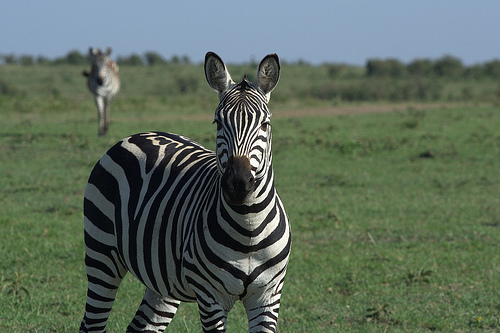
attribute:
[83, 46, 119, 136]
zebra — white , black , striped 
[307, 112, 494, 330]
grass — long , green, yellow 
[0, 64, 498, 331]
grass — yellow , green , long , brown , short 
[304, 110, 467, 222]
grass — yellow , green , long 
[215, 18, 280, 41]
clouds — white 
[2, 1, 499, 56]
sky — blue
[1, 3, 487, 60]
sky — blue 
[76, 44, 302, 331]
zebra — white , black , striped 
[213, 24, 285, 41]
clouds — white 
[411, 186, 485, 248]
grass — short , green, brown 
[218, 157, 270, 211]
nose — black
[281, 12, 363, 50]
sky — blue 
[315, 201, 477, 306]
grass — long , green , yellow 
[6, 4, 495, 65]
clouds — white 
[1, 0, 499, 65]
sky — blue 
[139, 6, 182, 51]
clouds — white 